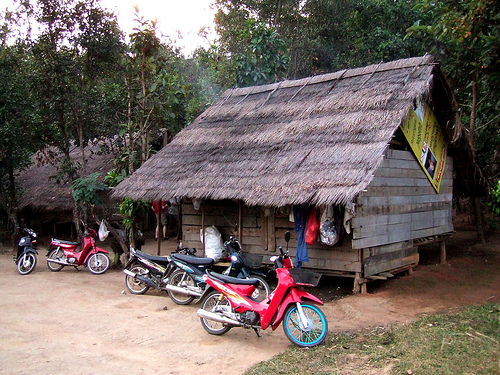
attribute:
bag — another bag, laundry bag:
[193, 213, 230, 272]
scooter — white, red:
[194, 240, 329, 344]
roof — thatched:
[170, 85, 420, 218]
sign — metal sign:
[401, 101, 446, 191]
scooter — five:
[202, 254, 314, 337]